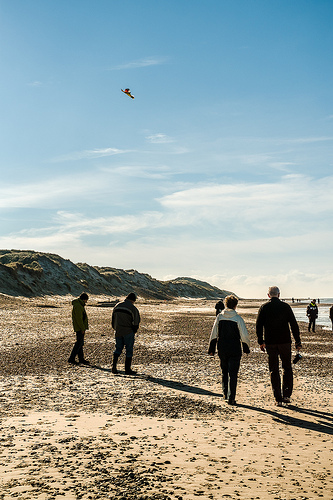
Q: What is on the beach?
A: Rocks.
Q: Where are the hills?
A: By the beach.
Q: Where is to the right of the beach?
A: Water.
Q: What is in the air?
A: A kite.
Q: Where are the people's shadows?
A: On the beach.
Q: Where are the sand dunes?
A: To the left of the beach.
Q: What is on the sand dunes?
A: Plants and bushes.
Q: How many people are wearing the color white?
A: One.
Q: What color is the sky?
A: Blue.